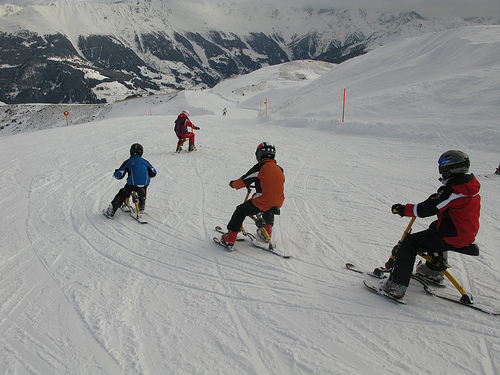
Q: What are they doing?
A: Skiing.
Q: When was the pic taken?
A: During the day.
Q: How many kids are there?
A: 4.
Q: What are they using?
A: Skiing bikes.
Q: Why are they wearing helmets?
A: For protection.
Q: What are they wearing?
A: Skiing shoes.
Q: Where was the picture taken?
A: Mountain.